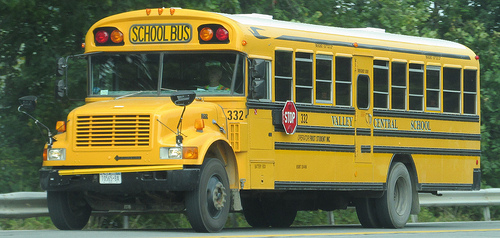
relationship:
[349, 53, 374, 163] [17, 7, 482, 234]
door on side of bus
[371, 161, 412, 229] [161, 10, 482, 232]
tire on driver's side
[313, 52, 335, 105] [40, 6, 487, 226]
window on bus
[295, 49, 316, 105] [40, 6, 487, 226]
open window on bus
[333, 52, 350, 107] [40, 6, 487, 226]
window on bus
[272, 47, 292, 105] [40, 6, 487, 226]
window on bus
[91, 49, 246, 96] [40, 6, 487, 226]
windshield of bus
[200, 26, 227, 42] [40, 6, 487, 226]
light on front of bus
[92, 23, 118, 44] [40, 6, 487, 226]
light on front of bus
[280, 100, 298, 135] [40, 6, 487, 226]
sign on side of bus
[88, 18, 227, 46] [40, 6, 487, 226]
lights at top of bus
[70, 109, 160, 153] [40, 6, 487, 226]
lines on front of bus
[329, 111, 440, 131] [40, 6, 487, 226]
writing on bus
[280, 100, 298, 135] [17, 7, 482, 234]
sign on side of bus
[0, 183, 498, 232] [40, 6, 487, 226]
guard rail by bus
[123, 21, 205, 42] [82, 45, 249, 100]
words are above windshield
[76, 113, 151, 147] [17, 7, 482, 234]
grill in front of bus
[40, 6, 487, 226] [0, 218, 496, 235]
bus on road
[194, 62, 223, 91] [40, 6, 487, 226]
man driving bus